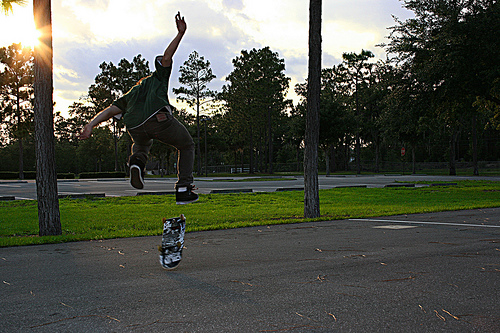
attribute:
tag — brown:
[154, 101, 175, 135]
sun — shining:
[18, 20, 58, 54]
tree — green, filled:
[215, 53, 295, 151]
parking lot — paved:
[0, 169, 472, 210]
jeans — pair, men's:
[121, 108, 198, 184]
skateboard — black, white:
[154, 210, 192, 272]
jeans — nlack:
[121, 111, 198, 191]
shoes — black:
[122, 156, 202, 204]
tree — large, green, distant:
[224, 44, 293, 177]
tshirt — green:
[126, 77, 168, 117]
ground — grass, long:
[393, 115, 453, 182]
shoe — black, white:
[176, 192, 201, 202]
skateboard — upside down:
[151, 203, 197, 279]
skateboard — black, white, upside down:
[156, 211, 183, 271]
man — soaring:
[73, 6, 217, 201]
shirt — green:
[110, 52, 175, 132]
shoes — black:
[109, 150, 191, 207]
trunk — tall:
[32, 0, 62, 236]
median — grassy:
[1, 177, 498, 246]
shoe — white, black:
[129, 145, 146, 198]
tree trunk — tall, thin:
[299, 0, 334, 225]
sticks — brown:
[441, 303, 466, 324]